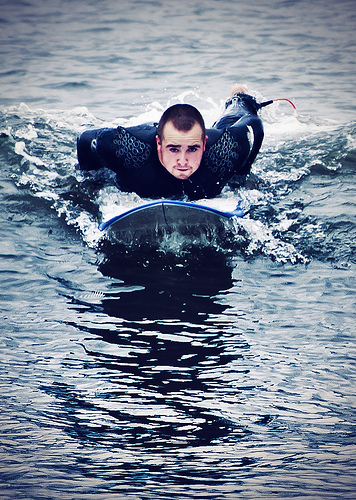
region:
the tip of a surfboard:
[97, 196, 237, 236]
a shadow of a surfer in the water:
[71, 308, 300, 456]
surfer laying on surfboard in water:
[66, 90, 302, 271]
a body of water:
[0, 2, 355, 77]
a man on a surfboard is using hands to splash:
[68, 86, 281, 242]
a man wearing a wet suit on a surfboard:
[78, 94, 260, 191]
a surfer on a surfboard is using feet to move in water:
[60, 80, 276, 244]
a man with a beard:
[155, 160, 198, 179]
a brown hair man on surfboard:
[155, 95, 200, 181]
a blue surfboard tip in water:
[98, 192, 243, 245]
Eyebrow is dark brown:
[164, 142, 183, 149]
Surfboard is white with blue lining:
[94, 192, 248, 236]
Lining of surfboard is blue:
[96, 191, 251, 231]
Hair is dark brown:
[158, 103, 204, 140]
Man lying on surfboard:
[72, 80, 263, 200]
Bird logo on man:
[225, 90, 258, 113]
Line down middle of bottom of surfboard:
[159, 203, 172, 230]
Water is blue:
[1, 2, 354, 498]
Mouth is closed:
[173, 166, 193, 172]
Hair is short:
[158, 103, 206, 142]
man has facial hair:
[154, 101, 211, 186]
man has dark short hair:
[147, 101, 204, 188]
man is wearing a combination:
[65, 86, 274, 206]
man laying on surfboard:
[67, 81, 292, 271]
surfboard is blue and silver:
[92, 192, 267, 257]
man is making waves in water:
[8, 89, 344, 282]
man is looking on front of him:
[63, 71, 277, 201]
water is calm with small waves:
[3, 0, 340, 114]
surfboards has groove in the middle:
[79, 178, 254, 243]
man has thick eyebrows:
[144, 101, 221, 199]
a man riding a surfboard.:
[76, 81, 295, 257]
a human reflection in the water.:
[42, 270, 262, 459]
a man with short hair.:
[140, 94, 221, 188]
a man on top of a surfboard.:
[88, 179, 250, 246]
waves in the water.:
[239, 104, 354, 257]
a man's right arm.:
[74, 117, 155, 221]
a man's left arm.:
[209, 72, 267, 210]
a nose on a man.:
[175, 152, 191, 168]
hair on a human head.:
[150, 102, 215, 141]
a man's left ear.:
[196, 127, 214, 159]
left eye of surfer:
[183, 145, 200, 164]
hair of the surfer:
[156, 103, 235, 146]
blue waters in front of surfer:
[83, 416, 253, 498]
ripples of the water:
[220, 406, 349, 489]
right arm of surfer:
[65, 119, 141, 174]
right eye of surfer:
[165, 142, 190, 165]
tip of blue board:
[126, 180, 203, 232]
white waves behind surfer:
[53, 93, 147, 136]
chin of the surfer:
[172, 167, 197, 184]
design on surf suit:
[103, 121, 164, 175]